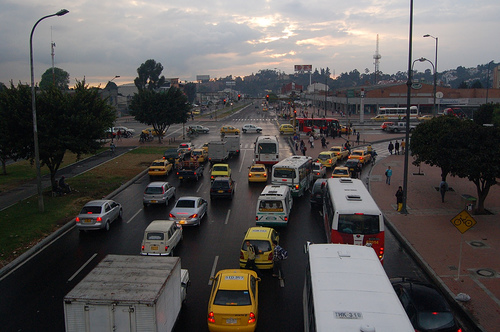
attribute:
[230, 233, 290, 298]
men — walking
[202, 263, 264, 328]
taxi cab — yellow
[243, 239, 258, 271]
men — walking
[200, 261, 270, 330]
cab — yellow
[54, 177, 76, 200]
person — sitting down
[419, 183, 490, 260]
sign — yellow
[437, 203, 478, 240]
sign — yellow, black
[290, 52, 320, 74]
sign — red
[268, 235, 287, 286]
person — standing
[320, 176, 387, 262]
bus — red, white, passenger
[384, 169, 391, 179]
shirt — blue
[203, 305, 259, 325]
lights — tail